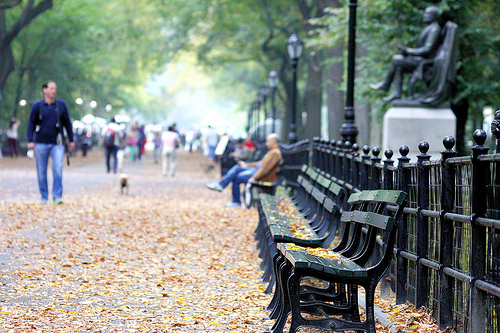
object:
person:
[214, 132, 283, 208]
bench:
[267, 189, 407, 331]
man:
[24, 79, 76, 207]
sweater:
[28, 100, 72, 143]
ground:
[0, 174, 294, 332]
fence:
[283, 127, 498, 330]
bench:
[254, 164, 358, 295]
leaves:
[174, 310, 188, 319]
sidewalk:
[0, 142, 498, 330]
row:
[247, 161, 400, 331]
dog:
[119, 172, 130, 197]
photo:
[5, 7, 494, 329]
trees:
[0, 0, 189, 143]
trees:
[173, 0, 303, 135]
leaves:
[146, 57, 158, 66]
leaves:
[213, 41, 228, 55]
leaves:
[362, 21, 382, 35]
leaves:
[70, 57, 84, 67]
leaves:
[307, 50, 318, 58]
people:
[156, 121, 185, 178]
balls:
[469, 125, 490, 146]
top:
[251, 148, 283, 186]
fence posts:
[395, 142, 410, 303]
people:
[97, 117, 125, 172]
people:
[185, 129, 202, 154]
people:
[124, 121, 141, 162]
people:
[80, 114, 99, 156]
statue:
[372, 3, 470, 109]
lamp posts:
[288, 62, 299, 150]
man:
[371, 5, 449, 100]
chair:
[383, 18, 460, 107]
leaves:
[43, 232, 61, 240]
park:
[2, 3, 498, 328]